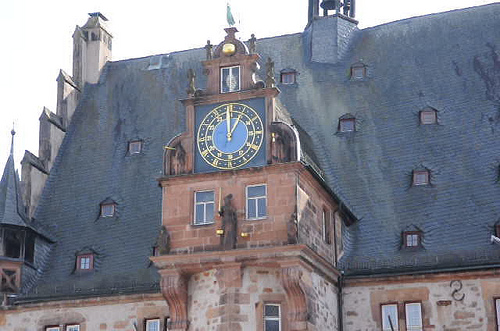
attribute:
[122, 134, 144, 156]
small window — on a roof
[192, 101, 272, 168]
clock — blue